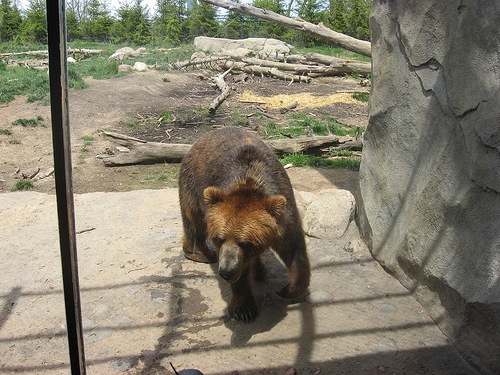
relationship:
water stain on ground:
[135, 267, 204, 353] [113, 213, 135, 232]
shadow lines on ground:
[318, 264, 395, 331] [113, 213, 135, 232]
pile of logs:
[190, 34, 311, 81] [206, 66, 277, 119]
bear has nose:
[173, 132, 317, 316] [218, 267, 234, 279]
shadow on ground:
[263, 288, 322, 329] [113, 213, 135, 232]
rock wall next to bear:
[387, 28, 482, 142] [173, 132, 317, 316]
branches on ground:
[232, 104, 292, 135] [113, 213, 135, 232]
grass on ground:
[18, 68, 25, 91] [113, 213, 135, 232]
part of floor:
[13, 207, 27, 219] [88, 203, 138, 235]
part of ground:
[13, 207, 27, 219] [113, 213, 135, 232]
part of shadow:
[13, 207, 27, 219] [263, 288, 322, 329]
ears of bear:
[193, 181, 290, 228] [173, 132, 317, 316]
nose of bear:
[218, 263, 247, 292] [173, 132, 317, 316]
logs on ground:
[206, 66, 277, 119] [113, 213, 135, 232]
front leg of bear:
[279, 249, 312, 295] [173, 132, 317, 316]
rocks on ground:
[113, 43, 157, 90] [113, 213, 135, 232]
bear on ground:
[173, 132, 317, 316] [113, 213, 135, 232]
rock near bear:
[306, 193, 363, 260] [173, 132, 317, 316]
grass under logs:
[18, 68, 25, 91] [206, 66, 277, 119]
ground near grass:
[113, 213, 135, 232] [18, 68, 25, 91]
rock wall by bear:
[387, 28, 482, 142] [173, 132, 317, 316]